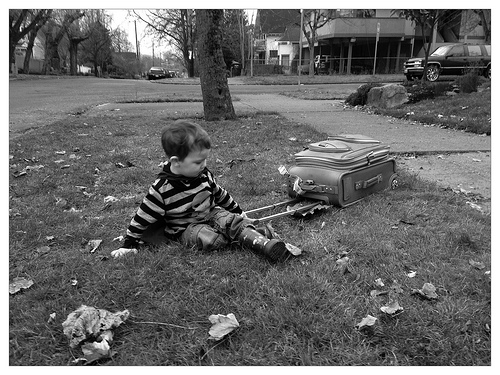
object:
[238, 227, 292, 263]
boots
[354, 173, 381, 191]
handle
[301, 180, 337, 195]
handle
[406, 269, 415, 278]
leaves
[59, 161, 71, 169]
leaves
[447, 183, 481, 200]
leaves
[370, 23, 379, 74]
shelves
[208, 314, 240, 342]
leaf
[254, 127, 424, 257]
luggage ground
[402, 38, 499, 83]
car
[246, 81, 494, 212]
sidewalk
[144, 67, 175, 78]
cars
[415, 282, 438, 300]
leaf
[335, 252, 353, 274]
leaf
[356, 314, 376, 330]
leaf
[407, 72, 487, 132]
grass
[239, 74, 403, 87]
grass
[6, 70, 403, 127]
road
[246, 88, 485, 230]
black top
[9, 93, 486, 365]
grass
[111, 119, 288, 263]
boy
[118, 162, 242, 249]
shirt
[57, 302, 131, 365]
big leaf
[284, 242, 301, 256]
leaf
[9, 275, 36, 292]
leaf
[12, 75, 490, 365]
ground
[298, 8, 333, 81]
leafless tree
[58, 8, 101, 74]
leafless tree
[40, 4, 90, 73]
leafless tree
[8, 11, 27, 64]
leafless tree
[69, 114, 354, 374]
patch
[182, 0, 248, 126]
tree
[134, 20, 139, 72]
pole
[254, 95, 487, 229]
side walk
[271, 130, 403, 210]
suitcase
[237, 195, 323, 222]
handle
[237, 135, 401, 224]
luggage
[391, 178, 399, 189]
wheels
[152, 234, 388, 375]
down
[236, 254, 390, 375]
curb